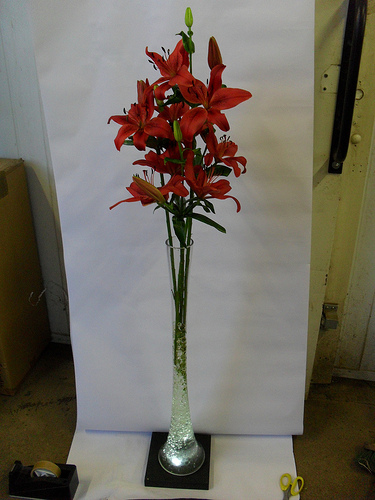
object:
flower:
[175, 61, 255, 137]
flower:
[199, 132, 252, 180]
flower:
[106, 169, 194, 211]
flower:
[108, 97, 180, 157]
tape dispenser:
[5, 459, 81, 498]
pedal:
[209, 87, 251, 110]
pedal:
[144, 47, 176, 76]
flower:
[108, 5, 252, 474]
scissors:
[274, 471, 302, 498]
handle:
[281, 472, 304, 493]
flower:
[139, 90, 208, 180]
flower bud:
[182, 6, 198, 27]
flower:
[111, 78, 166, 148]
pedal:
[167, 64, 197, 88]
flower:
[142, 38, 197, 101]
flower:
[182, 149, 242, 212]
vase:
[144, 235, 212, 491]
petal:
[111, 120, 138, 151]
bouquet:
[100, 1, 259, 244]